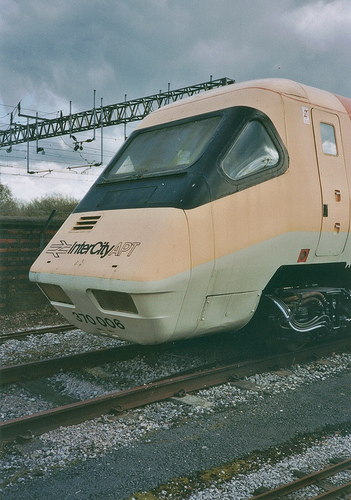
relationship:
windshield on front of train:
[104, 124, 282, 205] [29, 78, 345, 347]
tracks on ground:
[0, 341, 348, 446] [0, 334, 347, 497]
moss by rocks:
[126, 439, 267, 499] [217, 476, 274, 491]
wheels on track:
[267, 320, 341, 354] [1, 318, 349, 499]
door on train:
[310, 107, 349, 257] [17, 99, 338, 349]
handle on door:
[328, 184, 347, 239] [301, 102, 348, 262]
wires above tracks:
[2, 100, 119, 178] [0, 337, 351, 446]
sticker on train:
[301, 105, 311, 125] [29, 78, 345, 347]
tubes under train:
[285, 291, 334, 311] [29, 78, 345, 347]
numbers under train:
[75, 302, 141, 340] [29, 78, 345, 347]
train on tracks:
[29, 78, 345, 347] [16, 304, 337, 497]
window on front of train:
[93, 111, 284, 231] [2, 48, 350, 334]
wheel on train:
[270, 297, 309, 352] [28, 78, 351, 353]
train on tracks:
[28, 78, 351, 353] [16, 304, 337, 497]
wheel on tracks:
[270, 297, 309, 352] [16, 304, 337, 497]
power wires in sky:
[16, 103, 100, 177] [52, 15, 196, 61]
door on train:
[310, 107, 349, 257] [20, 70, 345, 333]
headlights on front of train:
[29, 273, 141, 323] [19, 68, 349, 410]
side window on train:
[319, 121, 338, 156] [29, 78, 345, 347]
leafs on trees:
[39, 190, 80, 207] [1, 179, 87, 217]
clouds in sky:
[0, 0, 351, 207] [1, 3, 349, 204]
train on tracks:
[29, 78, 345, 347] [0, 341, 348, 446]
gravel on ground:
[65, 397, 218, 448] [5, 278, 347, 498]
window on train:
[84, 107, 289, 193] [29, 78, 345, 347]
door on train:
[303, 96, 349, 259] [29, 78, 345, 347]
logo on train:
[43, 234, 145, 270] [29, 78, 345, 347]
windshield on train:
[98, 115, 290, 202] [29, 78, 345, 347]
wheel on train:
[269, 286, 350, 351] [29, 78, 345, 347]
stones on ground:
[3, 323, 349, 498] [5, 278, 347, 498]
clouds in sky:
[92, 22, 232, 82] [1, 3, 349, 204]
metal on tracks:
[48, 322, 199, 432] [14, 314, 347, 487]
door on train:
[310, 107, 349, 257] [17, 56, 349, 375]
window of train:
[221, 120, 278, 179] [29, 78, 345, 347]